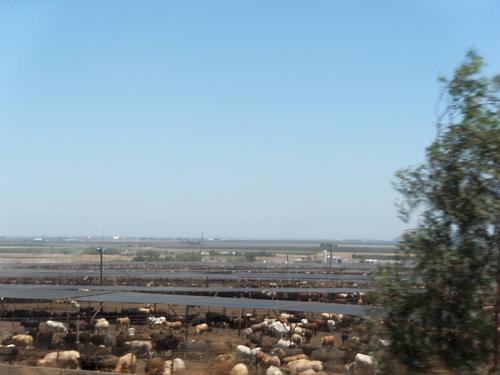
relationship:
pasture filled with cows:
[4, 249, 499, 374] [6, 293, 397, 375]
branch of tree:
[394, 170, 441, 219] [385, 53, 499, 372]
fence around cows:
[10, 299, 383, 374] [6, 293, 397, 375]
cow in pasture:
[47, 320, 70, 339] [4, 249, 499, 374]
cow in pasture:
[156, 332, 181, 356] [4, 249, 499, 374]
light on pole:
[95, 247, 105, 257] [93, 248, 107, 283]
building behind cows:
[328, 251, 347, 268] [6, 293, 397, 375]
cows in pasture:
[6, 293, 397, 375] [4, 249, 499, 374]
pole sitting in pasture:
[93, 248, 107, 283] [4, 249, 499, 374]